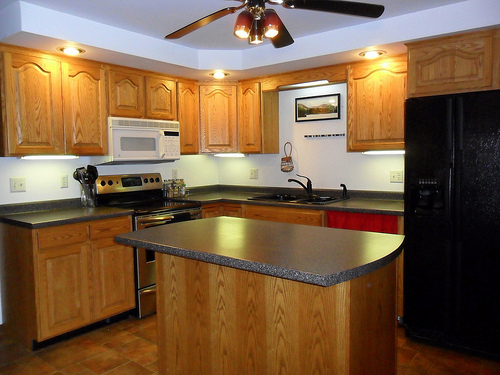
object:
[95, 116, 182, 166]
microwave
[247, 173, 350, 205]
sink faucet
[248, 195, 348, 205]
sink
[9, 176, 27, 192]
switch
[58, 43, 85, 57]
lamps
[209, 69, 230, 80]
round light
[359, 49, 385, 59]
round light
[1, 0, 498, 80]
ceiling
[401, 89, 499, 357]
black fridge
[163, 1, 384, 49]
ceiling fan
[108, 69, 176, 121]
cabinet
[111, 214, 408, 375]
counter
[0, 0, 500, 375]
kitchen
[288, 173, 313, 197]
faucet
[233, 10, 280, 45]
lights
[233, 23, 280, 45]
light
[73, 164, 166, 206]
stove